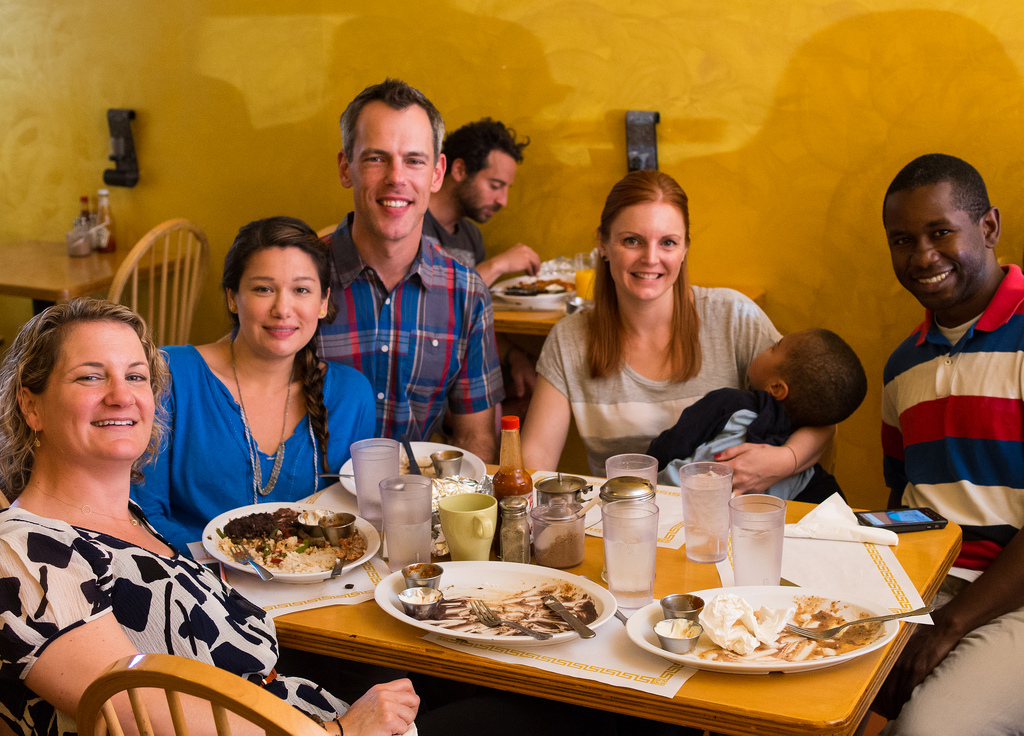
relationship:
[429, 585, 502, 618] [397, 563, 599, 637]
plate has dirty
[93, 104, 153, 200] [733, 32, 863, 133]
accessory on wall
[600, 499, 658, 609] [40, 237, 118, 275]
clear glass on table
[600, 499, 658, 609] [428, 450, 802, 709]
clear glass on top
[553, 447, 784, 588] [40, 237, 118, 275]
cups on table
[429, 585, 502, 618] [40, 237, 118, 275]
plate on table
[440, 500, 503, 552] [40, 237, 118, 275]
yellow mug on table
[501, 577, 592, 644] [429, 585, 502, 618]
silver fork on plate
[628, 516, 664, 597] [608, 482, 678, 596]
clear glass of water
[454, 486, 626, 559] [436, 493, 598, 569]
bunch of bunch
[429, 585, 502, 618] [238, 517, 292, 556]
plate of rice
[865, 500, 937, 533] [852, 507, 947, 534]
black cell black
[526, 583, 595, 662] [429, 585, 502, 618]
dirty knife on plate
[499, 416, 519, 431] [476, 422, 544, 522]
lid on hot sauce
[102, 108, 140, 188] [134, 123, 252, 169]
accessory on side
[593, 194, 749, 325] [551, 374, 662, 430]
woman smiling in black and white shir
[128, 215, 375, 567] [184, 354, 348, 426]
sitting woman sitting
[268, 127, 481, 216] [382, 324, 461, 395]
man in plaid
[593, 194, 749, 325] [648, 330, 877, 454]
woman holding child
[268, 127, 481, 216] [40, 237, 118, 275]
man at table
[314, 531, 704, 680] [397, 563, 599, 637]
dinner table covered in dirty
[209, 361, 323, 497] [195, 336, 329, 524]
silver necklace around girls neck